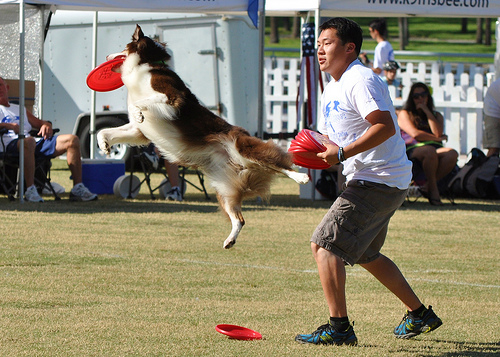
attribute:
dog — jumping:
[97, 24, 310, 249]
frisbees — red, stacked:
[285, 125, 335, 170]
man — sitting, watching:
[0, 76, 102, 204]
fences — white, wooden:
[265, 59, 500, 199]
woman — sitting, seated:
[395, 81, 459, 205]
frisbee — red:
[213, 321, 265, 343]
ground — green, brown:
[3, 159, 499, 356]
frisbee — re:
[83, 57, 131, 95]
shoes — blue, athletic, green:
[294, 322, 359, 349]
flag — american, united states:
[298, 16, 324, 187]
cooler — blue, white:
[78, 155, 141, 198]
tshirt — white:
[316, 60, 415, 191]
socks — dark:
[327, 316, 353, 331]